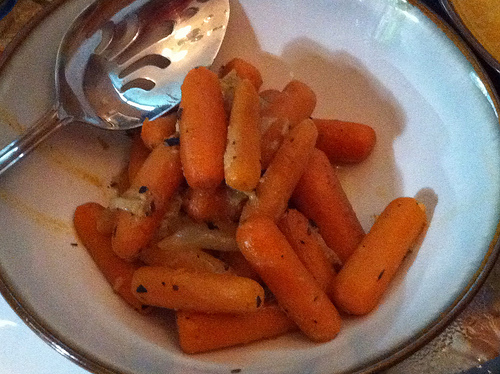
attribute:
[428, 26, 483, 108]
trim — in picture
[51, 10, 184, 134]
spoon — in picture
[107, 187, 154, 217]
onion — in picture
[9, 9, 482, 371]
bowl — in picture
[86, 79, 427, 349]
food — in picture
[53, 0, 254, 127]
spoon — in picture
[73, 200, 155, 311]
carrots — orange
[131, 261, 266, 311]
carrots — orange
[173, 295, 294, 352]
carrots — orange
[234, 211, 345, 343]
carrots — orange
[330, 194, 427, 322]
carrots — orange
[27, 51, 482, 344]
plate — round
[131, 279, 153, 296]
black pepper — in picture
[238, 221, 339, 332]
orange piece — in picture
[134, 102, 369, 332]
carrots — cooked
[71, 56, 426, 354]
carrots — cooked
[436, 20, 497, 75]
utensil — in picture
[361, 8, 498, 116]
plate — white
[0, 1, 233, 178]
spoon — in picture, silver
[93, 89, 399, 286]
carrots — sauced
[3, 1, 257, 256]
spoon — in picture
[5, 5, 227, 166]
spoon — in picture